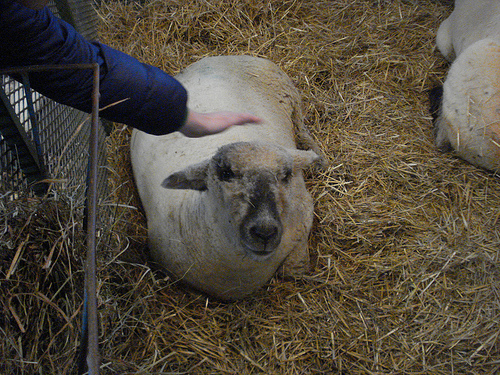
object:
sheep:
[129, 54, 328, 302]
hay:
[105, 27, 498, 374]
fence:
[0, 62, 106, 373]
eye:
[281, 167, 293, 184]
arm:
[0, 0, 188, 141]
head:
[161, 141, 320, 262]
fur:
[131, 55, 328, 303]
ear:
[282, 148, 325, 176]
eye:
[218, 163, 234, 182]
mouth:
[248, 248, 275, 256]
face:
[217, 157, 297, 253]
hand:
[179, 111, 264, 138]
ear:
[160, 158, 208, 192]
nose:
[249, 225, 279, 243]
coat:
[0, 0, 187, 136]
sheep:
[426, 0, 500, 170]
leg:
[277, 243, 312, 282]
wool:
[128, 52, 331, 300]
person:
[0, 0, 265, 138]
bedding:
[57, 12, 489, 366]